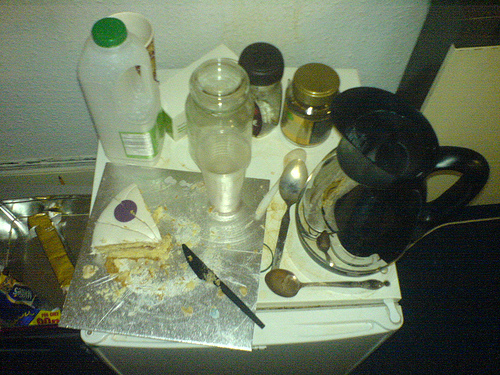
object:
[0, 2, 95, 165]
wall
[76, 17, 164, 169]
bottle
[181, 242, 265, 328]
knife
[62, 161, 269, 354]
tray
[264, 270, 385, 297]
spoon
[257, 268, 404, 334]
fridge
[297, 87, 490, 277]
kettle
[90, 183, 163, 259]
cake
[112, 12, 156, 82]
cup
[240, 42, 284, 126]
bottle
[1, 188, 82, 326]
sink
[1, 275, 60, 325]
paper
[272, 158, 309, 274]
spoon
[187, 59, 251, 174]
jar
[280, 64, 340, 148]
bottle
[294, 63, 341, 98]
lid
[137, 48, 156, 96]
handle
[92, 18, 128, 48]
cap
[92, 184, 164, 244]
frosting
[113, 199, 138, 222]
circle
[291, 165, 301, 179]
light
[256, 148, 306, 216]
spoon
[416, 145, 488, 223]
handle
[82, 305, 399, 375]
door